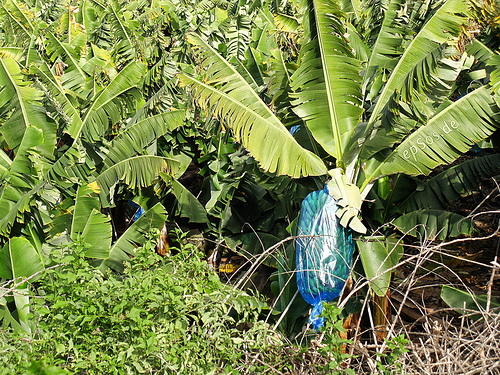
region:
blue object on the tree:
[290, 171, 377, 289]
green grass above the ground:
[76, 298, 181, 362]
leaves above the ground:
[41, 87, 165, 201]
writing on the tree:
[396, 106, 479, 169]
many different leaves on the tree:
[38, 23, 214, 134]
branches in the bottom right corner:
[315, 239, 487, 368]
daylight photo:
[8, 18, 384, 145]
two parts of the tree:
[314, 23, 339, 140]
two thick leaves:
[296, 37, 447, 111]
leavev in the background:
[21, 17, 151, 77]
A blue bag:
[287, 171, 357, 337]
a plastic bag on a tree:
[298, 180, 359, 332]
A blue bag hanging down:
[291, 177, 356, 344]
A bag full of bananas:
[298, 180, 353, 340]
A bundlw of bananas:
[298, 194, 348, 296]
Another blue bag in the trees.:
[128, 197, 143, 222]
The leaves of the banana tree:
[78, 61, 188, 216]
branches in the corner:
[419, 299, 499, 374]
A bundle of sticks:
[410, 294, 499, 372]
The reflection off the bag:
[310, 205, 343, 287]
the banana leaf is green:
[159, 35, 316, 197]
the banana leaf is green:
[191, 67, 363, 351]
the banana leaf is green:
[153, 8, 258, 179]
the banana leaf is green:
[209, 128, 316, 373]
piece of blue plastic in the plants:
[273, 155, 392, 362]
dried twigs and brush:
[358, 277, 494, 372]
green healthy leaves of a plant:
[170, 33, 377, 176]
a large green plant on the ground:
[165, 5, 497, 189]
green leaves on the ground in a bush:
[12, 227, 249, 367]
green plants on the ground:
[42, 27, 240, 172]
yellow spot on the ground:
[202, 247, 252, 285]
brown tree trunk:
[330, 271, 409, 373]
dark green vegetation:
[6, 24, 204, 181]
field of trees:
[53, 3, 408, 135]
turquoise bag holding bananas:
[296, 185, 353, 322]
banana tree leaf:
[296, 12, 363, 157]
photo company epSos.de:
[394, 112, 459, 168]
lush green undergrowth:
[43, 272, 222, 374]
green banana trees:
[84, 2, 498, 328]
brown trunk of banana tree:
[151, 222, 171, 257]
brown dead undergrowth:
[412, 307, 498, 374]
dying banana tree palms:
[53, 7, 90, 56]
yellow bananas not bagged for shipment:
[209, 246, 239, 277]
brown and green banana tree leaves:
[449, 2, 499, 57]